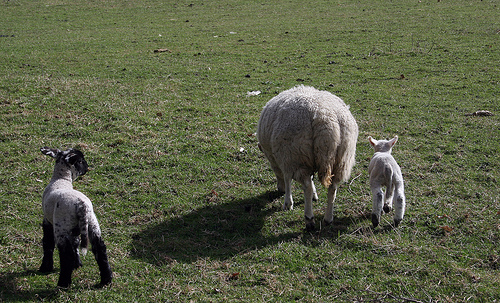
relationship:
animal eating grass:
[257, 84, 358, 231] [1, 2, 496, 299]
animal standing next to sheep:
[257, 84, 358, 231] [364, 132, 407, 228]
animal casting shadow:
[257, 84, 358, 231] [123, 183, 300, 267]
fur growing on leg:
[37, 215, 55, 274] [38, 219, 57, 276]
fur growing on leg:
[88, 232, 113, 287] [85, 231, 113, 287]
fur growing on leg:
[56, 235, 77, 289] [55, 235, 77, 287]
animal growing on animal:
[257, 84, 358, 231] [242, 56, 351, 208]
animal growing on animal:
[368, 136, 406, 229] [365, 134, 424, 209]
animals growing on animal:
[39, 146, 113, 292] [39, 145, 116, 292]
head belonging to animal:
[38, 129, 121, 186] [39, 145, 116, 292]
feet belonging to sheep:
[371, 221, 380, 228] [361, 132, 406, 230]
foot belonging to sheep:
[394, 218, 404, 226] [361, 132, 406, 230]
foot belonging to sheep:
[381, 206, 391, 214] [361, 132, 406, 230]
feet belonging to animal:
[306, 222, 317, 232] [257, 84, 358, 231]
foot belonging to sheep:
[99, 278, 112, 286] [33, 142, 118, 286]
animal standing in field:
[368, 136, 406, 229] [2, 0, 484, 300]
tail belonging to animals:
[73, 199, 91, 258] [39, 146, 113, 292]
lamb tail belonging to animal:
[313, 112, 340, 190] [257, 84, 358, 231]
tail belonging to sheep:
[383, 168, 391, 204] [362, 129, 411, 229]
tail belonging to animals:
[77, 202, 88, 256] [39, 146, 113, 292]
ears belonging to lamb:
[358, 123, 387, 155] [353, 118, 431, 247]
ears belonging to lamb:
[381, 118, 404, 147] [353, 118, 431, 247]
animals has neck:
[39, 146, 113, 292] [47, 161, 73, 185]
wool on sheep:
[276, 101, 306, 150] [251, 75, 362, 244]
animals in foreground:
[29, 78, 411, 293] [17, 76, 484, 301]